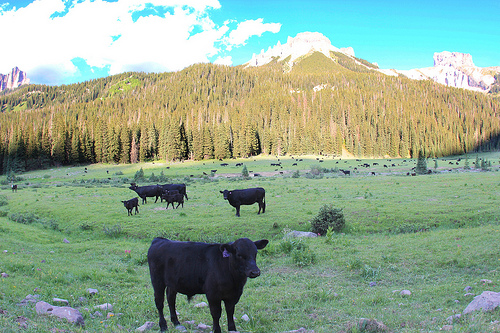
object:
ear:
[218, 244, 230, 258]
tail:
[262, 191, 265, 210]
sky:
[266, 7, 498, 49]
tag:
[222, 250, 229, 258]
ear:
[254, 239, 269, 249]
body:
[220, 187, 267, 217]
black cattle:
[148, 237, 270, 333]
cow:
[152, 183, 188, 203]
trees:
[154, 124, 188, 159]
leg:
[225, 300, 237, 329]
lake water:
[31, 171, 125, 174]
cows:
[129, 183, 163, 205]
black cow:
[162, 193, 188, 209]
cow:
[121, 197, 140, 217]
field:
[0, 154, 500, 332]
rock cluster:
[0, 64, 37, 89]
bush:
[308, 205, 346, 235]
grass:
[351, 187, 472, 231]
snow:
[264, 26, 317, 50]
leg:
[208, 294, 223, 331]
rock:
[449, 290, 500, 323]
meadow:
[3, 198, 79, 330]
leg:
[166, 292, 179, 323]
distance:
[0, 24, 500, 96]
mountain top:
[0, 28, 499, 168]